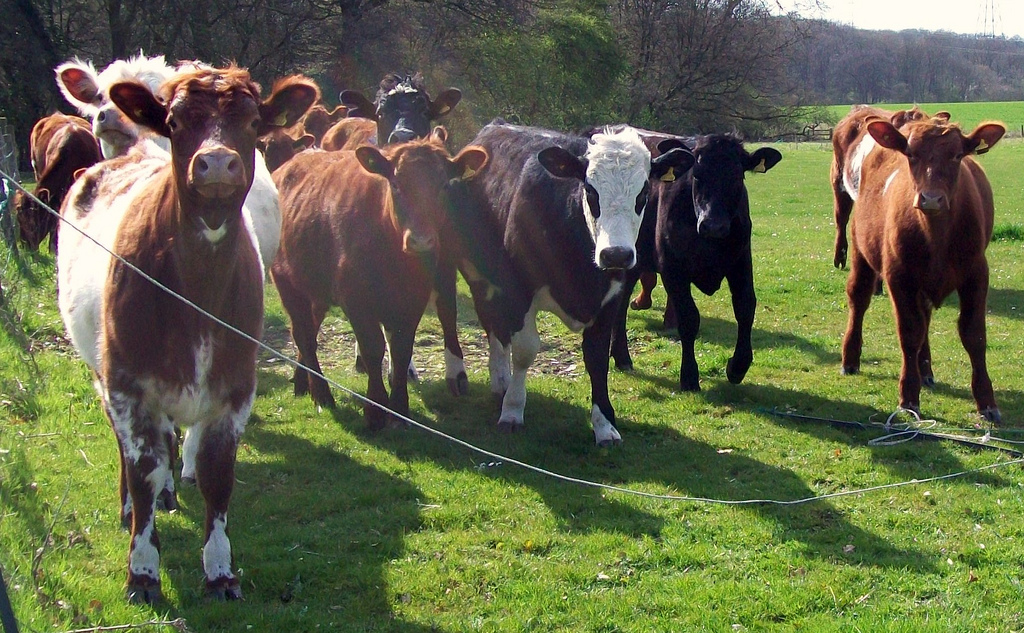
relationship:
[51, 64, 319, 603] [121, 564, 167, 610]
cow has hoof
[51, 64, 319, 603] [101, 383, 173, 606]
cow has leg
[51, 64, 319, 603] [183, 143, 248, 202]
cow has snout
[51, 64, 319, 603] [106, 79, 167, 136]
cow has ear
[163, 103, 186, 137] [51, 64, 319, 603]
eye on cow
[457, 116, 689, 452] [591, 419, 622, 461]
cow has hoof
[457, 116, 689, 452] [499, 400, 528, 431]
cow has hoof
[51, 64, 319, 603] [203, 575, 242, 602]
cow has hoof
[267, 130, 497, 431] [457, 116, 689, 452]
cow next to cow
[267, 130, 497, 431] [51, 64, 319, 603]
cow next to cow